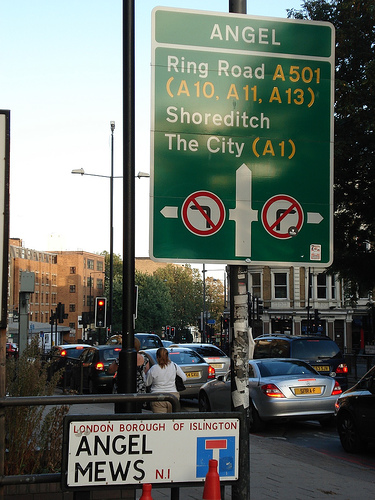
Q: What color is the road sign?
A: Green.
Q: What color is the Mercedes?
A: Silver.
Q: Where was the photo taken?
A: London.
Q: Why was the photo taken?
A: For a magazine.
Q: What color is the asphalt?
A: Black.